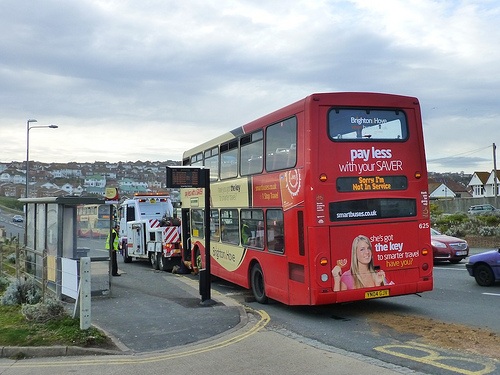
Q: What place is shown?
A: It is a street.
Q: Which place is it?
A: It is a street.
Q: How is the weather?
A: It is cloudy.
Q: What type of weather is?
A: It is cloudy.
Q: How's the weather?
A: It is cloudy.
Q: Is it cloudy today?
A: Yes, it is cloudy.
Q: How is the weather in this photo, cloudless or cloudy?
A: It is cloudy.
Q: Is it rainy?
A: No, it is cloudy.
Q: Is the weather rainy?
A: No, it is cloudy.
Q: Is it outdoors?
A: Yes, it is outdoors.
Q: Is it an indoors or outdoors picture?
A: It is outdoors.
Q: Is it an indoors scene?
A: No, it is outdoors.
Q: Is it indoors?
A: No, it is outdoors.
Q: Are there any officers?
A: No, there are no officers.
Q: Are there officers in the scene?
A: No, there are no officers.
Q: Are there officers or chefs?
A: No, there are no officers or chefs.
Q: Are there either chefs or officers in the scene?
A: No, there are no officers or chefs.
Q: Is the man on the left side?
A: Yes, the man is on the left of the image.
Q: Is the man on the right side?
A: No, the man is on the left of the image.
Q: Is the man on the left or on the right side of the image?
A: The man is on the left of the image.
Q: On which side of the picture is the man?
A: The man is on the left of the image.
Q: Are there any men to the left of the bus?
A: Yes, there is a man to the left of the bus.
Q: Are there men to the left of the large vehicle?
A: Yes, there is a man to the left of the bus.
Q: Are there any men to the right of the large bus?
A: No, the man is to the left of the bus.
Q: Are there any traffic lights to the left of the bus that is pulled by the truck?
A: No, there is a man to the left of the bus.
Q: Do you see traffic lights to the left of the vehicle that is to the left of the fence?
A: No, there is a man to the left of the bus.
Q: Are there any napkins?
A: No, there are no napkins.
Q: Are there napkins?
A: No, there are no napkins.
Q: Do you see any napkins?
A: No, there are no napkins.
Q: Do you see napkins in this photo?
A: No, there are no napkins.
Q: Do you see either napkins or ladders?
A: No, there are no napkins or ladders.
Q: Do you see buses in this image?
A: Yes, there is a bus.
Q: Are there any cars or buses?
A: Yes, there is a bus.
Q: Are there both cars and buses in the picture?
A: Yes, there are both a bus and a car.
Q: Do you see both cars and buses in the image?
A: Yes, there are both a bus and a car.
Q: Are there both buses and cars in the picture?
A: Yes, there are both a bus and a car.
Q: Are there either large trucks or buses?
A: Yes, there is a large bus.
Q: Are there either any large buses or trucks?
A: Yes, there is a large bus.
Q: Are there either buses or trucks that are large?
A: Yes, the bus is large.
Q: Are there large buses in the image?
A: Yes, there is a large bus.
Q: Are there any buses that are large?
A: Yes, there is a large bus.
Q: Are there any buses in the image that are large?
A: Yes, there is a bus that is large.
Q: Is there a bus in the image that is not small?
A: Yes, there is a large bus.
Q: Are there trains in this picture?
A: No, there are no trains.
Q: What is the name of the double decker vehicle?
A: The vehicle is a bus.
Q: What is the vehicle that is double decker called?
A: The vehicle is a bus.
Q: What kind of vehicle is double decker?
A: The vehicle is a bus.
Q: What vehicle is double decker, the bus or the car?
A: The bus is double decker.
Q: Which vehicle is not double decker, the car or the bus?
A: The car is not double decker.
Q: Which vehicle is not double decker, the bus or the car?
A: The car is not double decker.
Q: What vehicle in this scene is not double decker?
A: The vehicle is a car.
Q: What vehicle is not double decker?
A: The vehicle is a car.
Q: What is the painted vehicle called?
A: The vehicle is a bus.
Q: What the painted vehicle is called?
A: The vehicle is a bus.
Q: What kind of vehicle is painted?
A: The vehicle is a bus.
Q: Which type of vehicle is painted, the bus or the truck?
A: The bus is painted.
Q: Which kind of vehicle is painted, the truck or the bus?
A: The bus is painted.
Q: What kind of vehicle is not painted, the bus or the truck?
A: The truck is not painted.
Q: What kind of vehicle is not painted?
A: The vehicle is a truck.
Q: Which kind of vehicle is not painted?
A: The vehicle is a truck.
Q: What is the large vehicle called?
A: The vehicle is a bus.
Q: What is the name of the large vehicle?
A: The vehicle is a bus.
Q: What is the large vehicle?
A: The vehicle is a bus.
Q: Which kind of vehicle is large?
A: The vehicle is a bus.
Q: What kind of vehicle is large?
A: The vehicle is a bus.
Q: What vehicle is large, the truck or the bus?
A: The bus is large.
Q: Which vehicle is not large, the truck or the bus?
A: The truck is not large.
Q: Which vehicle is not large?
A: The vehicle is a truck.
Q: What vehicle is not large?
A: The vehicle is a truck.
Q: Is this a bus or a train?
A: This is a bus.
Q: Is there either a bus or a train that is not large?
A: No, there is a bus but it is large.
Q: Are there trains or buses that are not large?
A: No, there is a bus but it is large.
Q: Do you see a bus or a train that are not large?
A: No, there is a bus but it is large.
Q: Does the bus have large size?
A: Yes, the bus is large.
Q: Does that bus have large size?
A: Yes, the bus is large.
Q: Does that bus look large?
A: Yes, the bus is large.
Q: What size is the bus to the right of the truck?
A: The bus is large.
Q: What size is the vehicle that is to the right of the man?
A: The bus is large.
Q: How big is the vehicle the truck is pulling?
A: The bus is large.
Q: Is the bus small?
A: No, the bus is large.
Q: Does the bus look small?
A: No, the bus is large.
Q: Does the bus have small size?
A: No, the bus is large.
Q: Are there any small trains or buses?
A: No, there is a bus but it is large.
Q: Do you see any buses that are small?
A: No, there is a bus but it is large.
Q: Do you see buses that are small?
A: No, there is a bus but it is large.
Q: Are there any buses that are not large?
A: No, there is a bus but it is large.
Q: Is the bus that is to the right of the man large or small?
A: The bus is large.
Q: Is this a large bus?
A: Yes, this is a large bus.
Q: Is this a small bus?
A: No, this is a large bus.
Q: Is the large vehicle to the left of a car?
A: Yes, the bus is to the left of a car.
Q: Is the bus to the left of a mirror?
A: No, the bus is to the left of a car.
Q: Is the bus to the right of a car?
A: No, the bus is to the left of a car.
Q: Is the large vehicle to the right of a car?
A: No, the bus is to the left of a car.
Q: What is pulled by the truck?
A: The bus is pulled by the truck.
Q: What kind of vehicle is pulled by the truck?
A: The vehicle is a bus.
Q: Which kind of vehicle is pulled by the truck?
A: The vehicle is a bus.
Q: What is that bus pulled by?
A: The bus is pulled by the truck.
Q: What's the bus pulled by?
A: The bus is pulled by the truck.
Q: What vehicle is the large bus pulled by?
A: The bus is pulled by the truck.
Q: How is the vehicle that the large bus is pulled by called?
A: The vehicle is a truck.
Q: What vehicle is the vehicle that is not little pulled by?
A: The bus is pulled by the truck.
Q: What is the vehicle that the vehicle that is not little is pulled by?
A: The vehicle is a truck.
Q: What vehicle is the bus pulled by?
A: The bus is pulled by the truck.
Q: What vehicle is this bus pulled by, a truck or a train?
A: The bus is pulled by a truck.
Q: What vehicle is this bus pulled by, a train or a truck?
A: The bus is pulled by a truck.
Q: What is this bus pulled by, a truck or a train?
A: The bus is pulled by a truck.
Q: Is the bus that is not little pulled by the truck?
A: Yes, the bus is pulled by the truck.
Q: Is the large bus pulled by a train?
A: No, the bus is pulled by the truck.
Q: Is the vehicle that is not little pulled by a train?
A: No, the bus is pulled by the truck.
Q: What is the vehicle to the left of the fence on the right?
A: The vehicle is a bus.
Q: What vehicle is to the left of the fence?
A: The vehicle is a bus.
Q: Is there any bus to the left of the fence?
A: Yes, there is a bus to the left of the fence.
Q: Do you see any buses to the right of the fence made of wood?
A: No, the bus is to the left of the fence.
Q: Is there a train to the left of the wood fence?
A: No, there is a bus to the left of the fence.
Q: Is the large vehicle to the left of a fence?
A: Yes, the bus is to the left of a fence.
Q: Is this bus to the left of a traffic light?
A: No, the bus is to the left of a fence.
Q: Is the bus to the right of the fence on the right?
A: No, the bus is to the left of the fence.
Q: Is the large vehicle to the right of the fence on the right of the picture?
A: No, the bus is to the left of the fence.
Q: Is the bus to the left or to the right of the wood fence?
A: The bus is to the left of the fence.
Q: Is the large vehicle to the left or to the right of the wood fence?
A: The bus is to the left of the fence.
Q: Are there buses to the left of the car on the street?
A: Yes, there is a bus to the left of the car.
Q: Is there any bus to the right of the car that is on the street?
A: No, the bus is to the left of the car.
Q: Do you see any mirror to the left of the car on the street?
A: No, there is a bus to the left of the car.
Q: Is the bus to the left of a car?
A: Yes, the bus is to the left of a car.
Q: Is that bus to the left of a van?
A: No, the bus is to the left of a car.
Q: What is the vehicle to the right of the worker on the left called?
A: The vehicle is a bus.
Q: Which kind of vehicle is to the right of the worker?
A: The vehicle is a bus.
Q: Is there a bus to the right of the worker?
A: Yes, there is a bus to the right of the worker.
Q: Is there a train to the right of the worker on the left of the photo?
A: No, there is a bus to the right of the worker.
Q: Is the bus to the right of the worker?
A: Yes, the bus is to the right of the worker.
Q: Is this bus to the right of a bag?
A: No, the bus is to the right of the worker.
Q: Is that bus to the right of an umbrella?
A: No, the bus is to the right of a man.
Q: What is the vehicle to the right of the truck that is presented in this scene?
A: The vehicle is a bus.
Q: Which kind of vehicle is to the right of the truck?
A: The vehicle is a bus.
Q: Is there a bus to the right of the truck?
A: Yes, there is a bus to the right of the truck.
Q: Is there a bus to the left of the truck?
A: No, the bus is to the right of the truck.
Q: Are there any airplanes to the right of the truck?
A: No, there is a bus to the right of the truck.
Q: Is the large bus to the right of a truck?
A: Yes, the bus is to the right of a truck.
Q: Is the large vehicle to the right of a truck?
A: Yes, the bus is to the right of a truck.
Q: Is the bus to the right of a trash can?
A: No, the bus is to the right of a truck.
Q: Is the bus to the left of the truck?
A: No, the bus is to the right of the truck.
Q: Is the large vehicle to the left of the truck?
A: No, the bus is to the right of the truck.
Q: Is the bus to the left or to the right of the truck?
A: The bus is to the right of the truck.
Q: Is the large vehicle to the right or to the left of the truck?
A: The bus is to the right of the truck.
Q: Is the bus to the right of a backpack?
A: No, the bus is to the right of a man.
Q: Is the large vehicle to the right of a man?
A: Yes, the bus is to the right of a man.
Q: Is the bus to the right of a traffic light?
A: No, the bus is to the right of a man.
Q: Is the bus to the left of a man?
A: No, the bus is to the right of a man.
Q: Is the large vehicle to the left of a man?
A: No, the bus is to the right of a man.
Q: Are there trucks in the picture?
A: Yes, there is a truck.